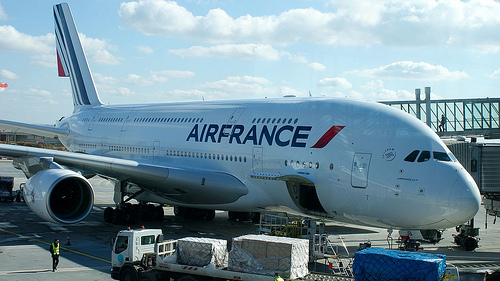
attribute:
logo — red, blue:
[187, 118, 348, 147]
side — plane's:
[63, 95, 460, 223]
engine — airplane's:
[17, 168, 94, 227]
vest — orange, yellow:
[50, 243, 61, 257]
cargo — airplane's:
[175, 228, 313, 280]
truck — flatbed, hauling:
[109, 221, 356, 279]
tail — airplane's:
[55, 4, 99, 113]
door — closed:
[351, 151, 370, 189]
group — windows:
[75, 110, 305, 167]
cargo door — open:
[250, 165, 325, 215]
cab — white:
[113, 223, 163, 268]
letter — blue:
[185, 118, 203, 142]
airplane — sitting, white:
[1, 0, 481, 238]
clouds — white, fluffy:
[2, 7, 500, 109]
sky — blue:
[0, 0, 497, 126]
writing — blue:
[183, 117, 313, 146]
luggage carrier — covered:
[348, 244, 451, 278]